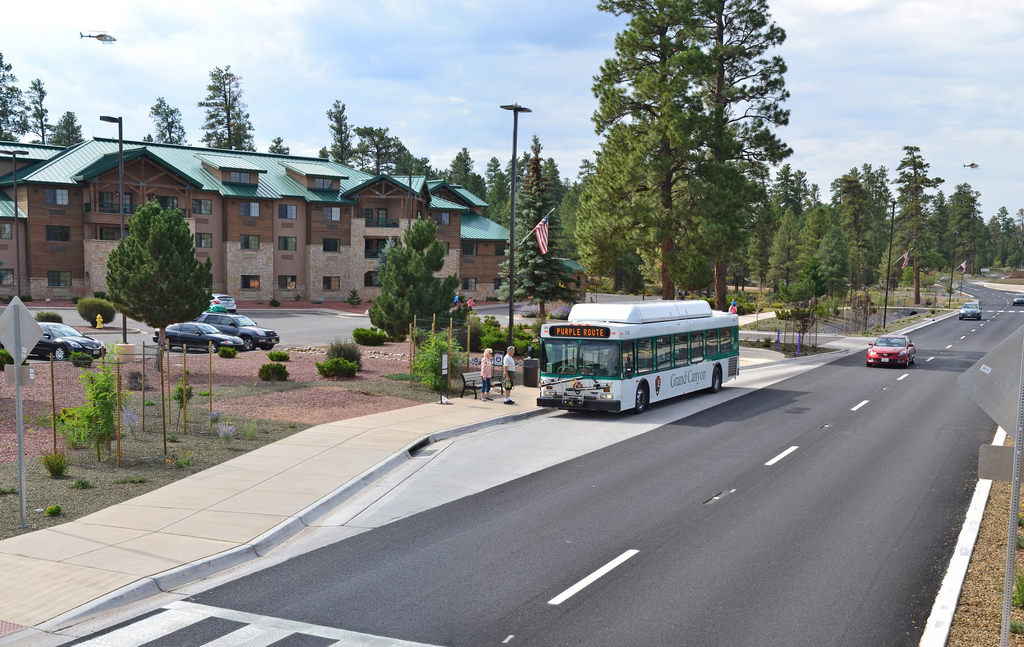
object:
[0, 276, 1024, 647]
road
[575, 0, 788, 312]
trees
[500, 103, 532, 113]
lamp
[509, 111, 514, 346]
post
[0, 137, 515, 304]
building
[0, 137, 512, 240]
roof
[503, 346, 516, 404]
man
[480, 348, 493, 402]
woman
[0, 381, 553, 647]
sidewalk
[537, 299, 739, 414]
bus stop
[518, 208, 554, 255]
flag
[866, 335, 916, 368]
red car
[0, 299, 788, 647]
street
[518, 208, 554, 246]
flagpole